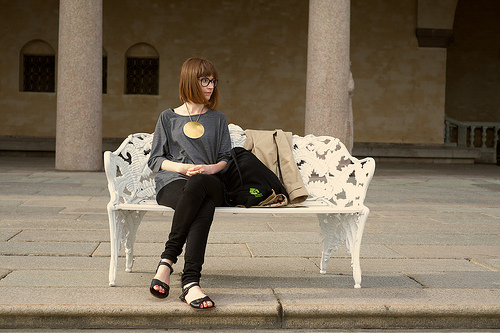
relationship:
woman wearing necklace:
[147, 54, 244, 314] [178, 99, 210, 140]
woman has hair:
[147, 54, 244, 314] [177, 56, 219, 109]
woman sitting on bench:
[147, 54, 244, 314] [100, 127, 381, 291]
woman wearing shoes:
[147, 54, 244, 314] [147, 257, 216, 310]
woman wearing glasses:
[147, 54, 244, 314] [196, 76, 217, 88]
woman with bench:
[147, 54, 244, 314] [100, 127, 381, 291]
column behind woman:
[53, 1, 109, 174] [147, 54, 244, 314]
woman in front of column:
[147, 54, 244, 314] [53, 1, 109, 174]